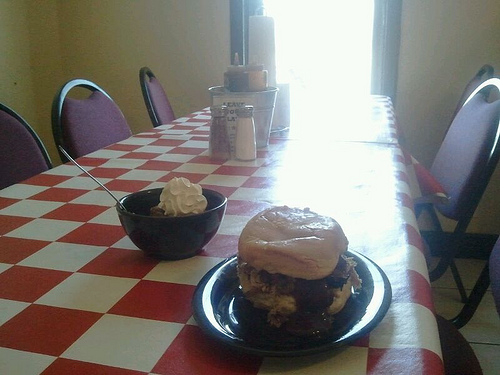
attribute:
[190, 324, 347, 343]
plate — blue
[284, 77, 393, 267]
sunlight — shining